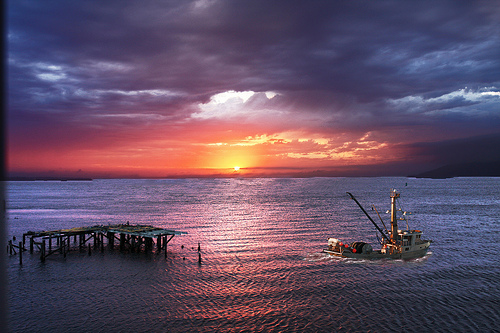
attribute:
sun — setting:
[229, 163, 246, 175]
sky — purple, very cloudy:
[7, 5, 497, 174]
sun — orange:
[233, 165, 240, 171]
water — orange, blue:
[168, 181, 344, 221]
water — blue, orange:
[14, 275, 498, 329]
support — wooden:
[26, 233, 168, 252]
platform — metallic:
[25, 221, 188, 265]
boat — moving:
[330, 182, 436, 272]